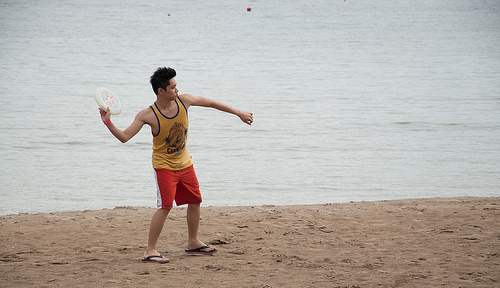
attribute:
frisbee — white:
[89, 82, 123, 113]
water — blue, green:
[279, 61, 411, 115]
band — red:
[102, 120, 111, 127]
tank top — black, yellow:
[142, 102, 205, 170]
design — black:
[158, 120, 193, 159]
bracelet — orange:
[101, 115, 113, 128]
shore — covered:
[261, 208, 468, 264]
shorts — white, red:
[155, 165, 202, 203]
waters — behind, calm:
[254, 6, 496, 173]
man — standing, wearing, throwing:
[95, 61, 256, 266]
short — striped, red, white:
[152, 164, 202, 207]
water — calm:
[1, 0, 498, 216]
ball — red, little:
[241, 1, 271, 15]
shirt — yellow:
[144, 97, 198, 171]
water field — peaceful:
[139, 22, 482, 212]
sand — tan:
[0, 193, 495, 284]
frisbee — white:
[88, 80, 133, 117]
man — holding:
[87, 60, 200, 163]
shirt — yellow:
[144, 95, 191, 172]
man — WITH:
[66, 62, 305, 230]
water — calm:
[251, 31, 478, 163]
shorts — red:
[146, 154, 213, 211]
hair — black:
[149, 65, 176, 97]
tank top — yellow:
[148, 97, 193, 170]